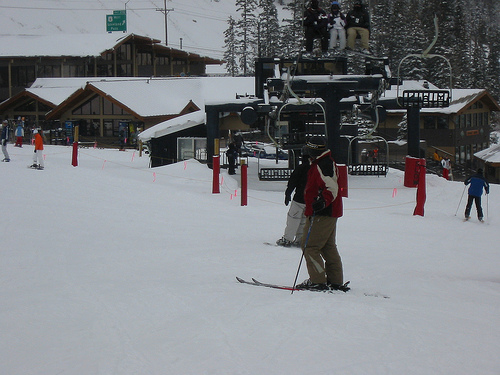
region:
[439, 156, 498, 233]
Person wearing a blue coat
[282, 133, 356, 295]
person wearing red and white coat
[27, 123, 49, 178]
Person wearing a red coat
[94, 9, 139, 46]
Green and white highway sign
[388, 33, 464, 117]
Metal ski lift covered in snow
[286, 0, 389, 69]
Group of people on a ski lift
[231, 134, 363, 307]
Person wearing coat and skis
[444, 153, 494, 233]
Person skiing down a hill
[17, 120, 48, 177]
Person wearing white hat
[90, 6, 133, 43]
Green sign with white writing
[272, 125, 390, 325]
A person on a pair of skis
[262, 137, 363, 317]
A person holding ski poles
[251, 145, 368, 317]
A person wearing ski boots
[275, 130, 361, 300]
A person wearing a red jacket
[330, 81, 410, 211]
A ski lift chair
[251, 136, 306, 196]
An empty ski lift chair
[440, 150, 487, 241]
A person wearing blue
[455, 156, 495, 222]
A person wearing blue on skis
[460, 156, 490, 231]
A person wearing blue holding ski poles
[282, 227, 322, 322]
A ski pole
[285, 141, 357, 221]
The person is wearing a red jacket.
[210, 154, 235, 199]
The bottom of the pole is red.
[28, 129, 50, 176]
The person is wearing an orange jacket.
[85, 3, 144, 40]
a green highway sign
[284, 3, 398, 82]
People riding a sky line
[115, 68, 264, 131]
The snow is on top of the roof.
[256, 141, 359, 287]
People skiing in the snow.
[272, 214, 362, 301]
The man has on tan pants.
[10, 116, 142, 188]
People are standing in front of the building.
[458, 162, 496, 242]
A person has on a blue jacket.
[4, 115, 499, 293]
People wearing snow skis.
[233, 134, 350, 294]
Skier holding a ski pole.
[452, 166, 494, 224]
Man skiing down a hill.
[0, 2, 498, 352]
Skiers at a ski resort.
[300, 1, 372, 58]
Skier riding a ski lift.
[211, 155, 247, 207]
Red poles in front of the ski lift.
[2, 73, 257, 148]
Ski resort establishment for renting equipment.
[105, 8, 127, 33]
Highway directional sign.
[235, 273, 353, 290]
Snow skis on the man's feet.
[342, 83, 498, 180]
Building in the ski resort.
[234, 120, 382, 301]
man wearing red jacket